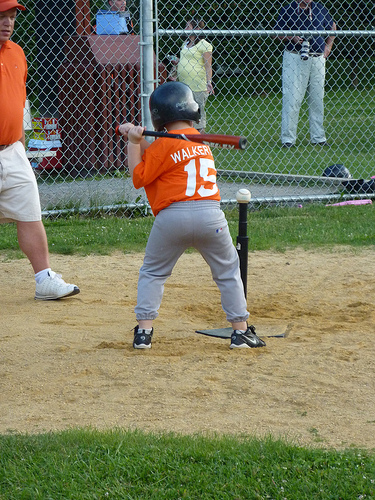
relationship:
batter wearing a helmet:
[115, 81, 266, 350] [139, 74, 219, 137]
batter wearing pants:
[115, 81, 266, 350] [136, 197, 249, 322]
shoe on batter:
[229, 321, 267, 349] [115, 81, 266, 350]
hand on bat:
[128, 124, 145, 137] [122, 121, 245, 159]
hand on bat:
[119, 121, 133, 135] [122, 121, 245, 159]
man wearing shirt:
[0, 5, 80, 300] [1, 39, 28, 154]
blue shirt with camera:
[271, 1, 336, 147] [290, 25, 314, 62]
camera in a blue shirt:
[290, 25, 314, 62] [278, 2, 335, 56]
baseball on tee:
[232, 183, 255, 207] [219, 199, 285, 342]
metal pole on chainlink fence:
[155, 27, 374, 36] [10, 2, 374, 215]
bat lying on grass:
[298, 198, 372, 209] [258, 217, 284, 227]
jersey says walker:
[131, 126, 216, 215] [168, 142, 213, 163]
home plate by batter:
[191, 317, 297, 345] [117, 72, 268, 356]